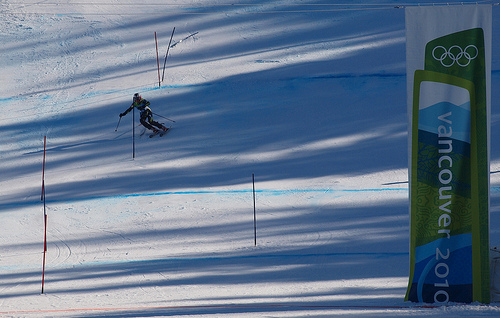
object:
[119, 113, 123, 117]
hand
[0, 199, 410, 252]
shade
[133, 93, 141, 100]
helmet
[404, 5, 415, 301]
edge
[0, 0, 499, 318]
ground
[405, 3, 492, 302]
banner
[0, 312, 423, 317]
line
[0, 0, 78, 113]
tracks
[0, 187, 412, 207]
marking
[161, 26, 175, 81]
pole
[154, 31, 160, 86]
pole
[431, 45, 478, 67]
sign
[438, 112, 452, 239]
name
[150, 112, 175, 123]
pole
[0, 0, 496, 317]
snow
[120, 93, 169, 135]
man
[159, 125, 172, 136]
skies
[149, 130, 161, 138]
skiis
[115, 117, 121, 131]
rod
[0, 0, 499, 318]
hill